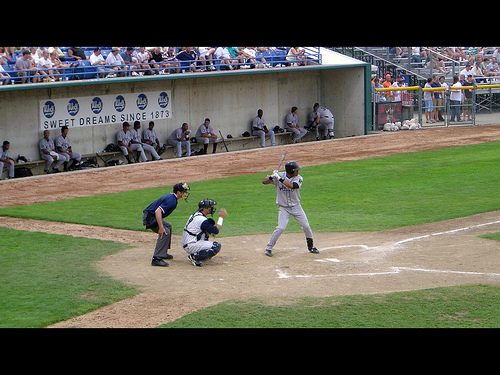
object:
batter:
[262, 159, 321, 259]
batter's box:
[263, 240, 398, 283]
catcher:
[180, 197, 228, 267]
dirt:
[0, 211, 500, 327]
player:
[36, 130, 66, 173]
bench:
[3, 122, 335, 178]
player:
[310, 101, 337, 142]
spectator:
[450, 76, 464, 121]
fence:
[373, 80, 499, 129]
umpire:
[141, 182, 191, 267]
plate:
[315, 256, 345, 264]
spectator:
[458, 66, 474, 83]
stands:
[351, 45, 499, 111]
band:
[217, 216, 226, 226]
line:
[269, 265, 399, 280]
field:
[1, 127, 500, 328]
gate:
[417, 84, 476, 128]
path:
[0, 211, 157, 248]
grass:
[1, 145, 499, 329]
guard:
[372, 80, 499, 91]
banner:
[37, 88, 177, 132]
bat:
[218, 130, 228, 154]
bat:
[273, 150, 288, 180]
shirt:
[143, 193, 179, 230]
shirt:
[381, 81, 395, 88]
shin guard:
[305, 238, 317, 254]